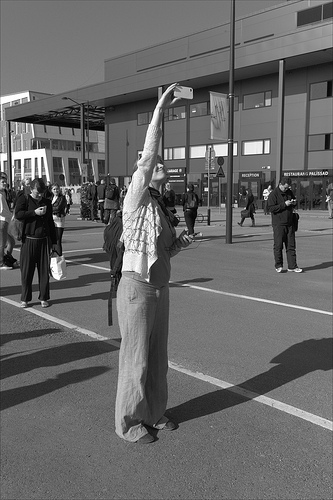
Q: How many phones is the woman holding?
A: One.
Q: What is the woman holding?
A: Phone.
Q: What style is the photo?
A: Black and white.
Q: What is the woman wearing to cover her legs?
A: Pants.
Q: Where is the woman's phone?
A: Her hand.